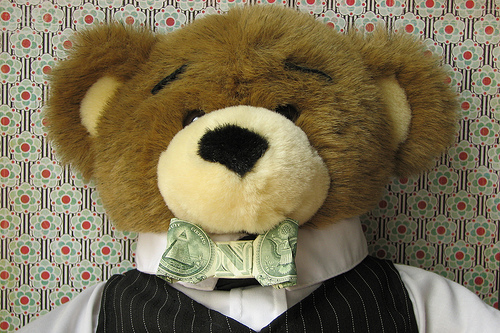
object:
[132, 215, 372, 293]
collar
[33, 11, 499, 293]
bear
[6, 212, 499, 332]
undershirt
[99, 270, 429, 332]
vest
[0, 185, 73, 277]
floral pattern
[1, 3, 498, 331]
backdrop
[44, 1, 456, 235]
teddy-bear's fur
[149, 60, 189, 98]
eye brow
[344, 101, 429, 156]
ground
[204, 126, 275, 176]
nose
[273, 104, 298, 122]
eye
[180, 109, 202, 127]
eye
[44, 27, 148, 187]
ear